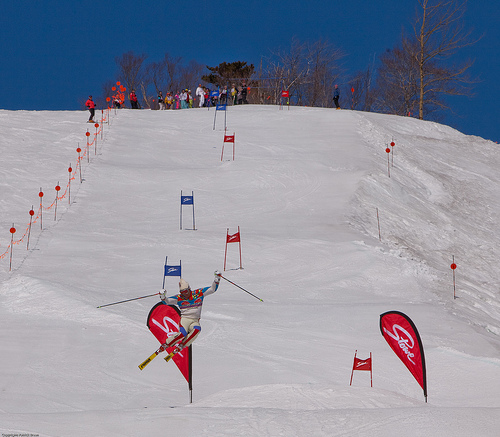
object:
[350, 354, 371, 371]
flag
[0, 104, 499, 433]
snow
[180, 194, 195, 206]
marker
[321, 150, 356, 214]
writing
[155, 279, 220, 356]
person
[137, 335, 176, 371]
skis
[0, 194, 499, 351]
hillside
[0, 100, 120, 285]
line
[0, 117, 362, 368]
slope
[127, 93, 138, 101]
coat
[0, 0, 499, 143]
sky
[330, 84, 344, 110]
person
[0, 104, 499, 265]
hill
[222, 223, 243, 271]
obstacle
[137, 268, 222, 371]
jumped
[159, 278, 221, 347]
uniform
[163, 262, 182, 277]
flags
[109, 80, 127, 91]
orange